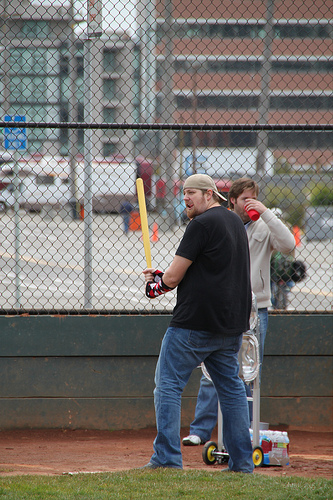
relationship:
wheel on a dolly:
[195, 433, 267, 470] [225, 290, 275, 470]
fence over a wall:
[5, 2, 330, 304] [6, 307, 331, 435]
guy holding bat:
[140, 169, 271, 482] [132, 173, 161, 283]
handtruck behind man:
[240, 289, 270, 464] [140, 169, 271, 482]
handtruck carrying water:
[240, 289, 270, 464] [251, 421, 298, 472]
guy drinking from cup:
[232, 178, 298, 295] [239, 203, 267, 222]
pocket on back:
[184, 323, 220, 348] [191, 333, 225, 351]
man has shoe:
[232, 178, 298, 295] [180, 432, 206, 449]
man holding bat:
[140, 169, 271, 482] [132, 173, 161, 283]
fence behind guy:
[5, 2, 330, 304] [140, 169, 255, 478]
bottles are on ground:
[251, 421, 298, 472] [2, 424, 330, 471]